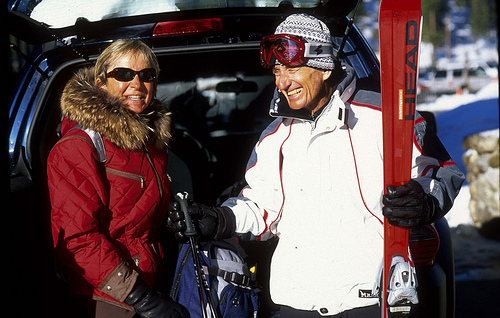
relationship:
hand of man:
[379, 176, 432, 231] [165, 14, 468, 317]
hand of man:
[379, 178, 438, 228] [165, 14, 468, 317]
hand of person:
[379, 178, 438, 228] [46, 37, 196, 317]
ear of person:
[93, 77, 107, 87] [46, 37, 196, 317]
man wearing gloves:
[167, 14, 462, 316] [371, 176, 442, 231]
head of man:
[271, 12, 334, 110] [165, 14, 468, 317]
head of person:
[95, 36, 160, 115] [45, 38, 171, 316]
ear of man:
[319, 65, 335, 82] [165, 14, 468, 317]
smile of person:
[122, 92, 151, 104] [45, 38, 171, 316]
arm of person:
[42, 143, 157, 313] [49, 36, 209, 317]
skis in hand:
[373, 7, 422, 317] [380, 177, 439, 236]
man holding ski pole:
[167, 14, 462, 316] [173, 191, 219, 318]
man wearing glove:
[167, 14, 462, 316] [164, 190, 221, 244]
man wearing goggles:
[165, 14, 468, 317] [260, 36, 304, 65]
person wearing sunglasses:
[46, 37, 195, 317] [101, 60, 183, 91]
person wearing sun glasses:
[46, 37, 195, 317] [101, 66, 163, 85]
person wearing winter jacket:
[46, 37, 195, 317] [43, 66, 172, 314]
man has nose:
[165, 14, 468, 317] [277, 68, 291, 90]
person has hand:
[46, 37, 196, 317] [169, 200, 221, 242]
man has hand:
[165, 14, 468, 317] [379, 177, 434, 227]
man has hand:
[165, 14, 468, 317] [121, 280, 192, 317]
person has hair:
[46, 37, 195, 317] [77, 44, 144, 76]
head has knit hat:
[267, 21, 333, 113] [222, 9, 404, 85]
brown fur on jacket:
[57, 67, 141, 146] [42, 113, 190, 313]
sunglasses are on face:
[105, 65, 159, 82] [108, 43, 148, 116]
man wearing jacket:
[167, 14, 462, 316] [221, 62, 466, 314]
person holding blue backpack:
[46, 37, 195, 317] [158, 233, 260, 316]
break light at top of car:
[152, 15, 227, 39] [6, 3, 474, 313]